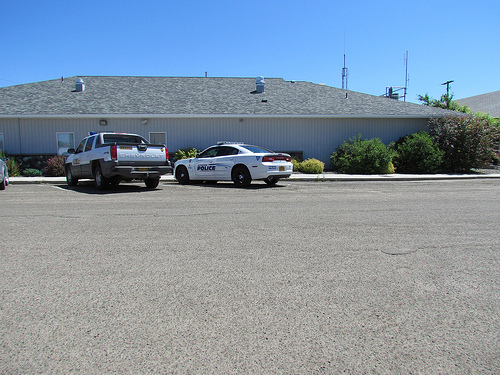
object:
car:
[173, 142, 293, 187]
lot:
[130, 212, 428, 318]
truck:
[61, 131, 171, 190]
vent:
[73, 75, 86, 94]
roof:
[133, 76, 179, 98]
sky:
[210, 17, 246, 40]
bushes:
[329, 133, 395, 174]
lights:
[109, 142, 118, 161]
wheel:
[94, 167, 104, 191]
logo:
[194, 162, 219, 172]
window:
[56, 131, 76, 153]